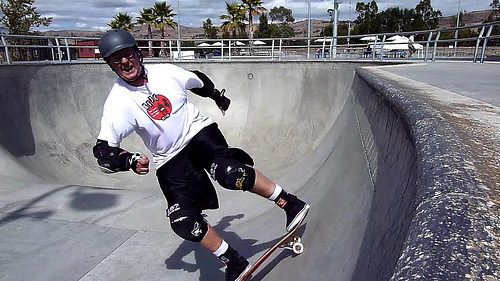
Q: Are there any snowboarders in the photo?
A: No, there are no snowboarders.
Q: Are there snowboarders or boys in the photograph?
A: No, there are no snowboarders or boys.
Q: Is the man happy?
A: Yes, the man is happy.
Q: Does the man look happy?
A: Yes, the man is happy.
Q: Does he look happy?
A: Yes, the man is happy.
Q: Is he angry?
A: No, the man is happy.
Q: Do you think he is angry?
A: No, the man is happy.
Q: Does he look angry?
A: No, the man is happy.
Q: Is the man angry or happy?
A: The man is happy.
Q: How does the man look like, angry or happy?
A: The man is happy.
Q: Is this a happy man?
A: Yes, this is a happy man.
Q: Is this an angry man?
A: No, this is a happy man.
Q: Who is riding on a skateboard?
A: The man is riding on a skateboard.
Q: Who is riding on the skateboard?
A: The man is riding on a skateboard.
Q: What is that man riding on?
A: The man is riding on a skateboard.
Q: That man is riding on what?
A: The man is riding on a skateboard.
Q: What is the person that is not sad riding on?
A: The man is riding on a skateboard.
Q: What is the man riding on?
A: The man is riding on a skateboard.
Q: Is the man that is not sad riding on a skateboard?
A: Yes, the man is riding on a skateboard.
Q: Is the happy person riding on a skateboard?
A: Yes, the man is riding on a skateboard.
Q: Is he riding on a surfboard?
A: No, the man is riding on a skateboard.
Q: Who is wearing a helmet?
A: The man is wearing a helmet.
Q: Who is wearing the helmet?
A: The man is wearing a helmet.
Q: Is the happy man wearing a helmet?
A: Yes, the man is wearing a helmet.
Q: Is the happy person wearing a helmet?
A: Yes, the man is wearing a helmet.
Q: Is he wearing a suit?
A: No, the man is wearing a helmet.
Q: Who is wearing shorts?
A: The man is wearing shorts.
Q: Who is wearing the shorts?
A: The man is wearing shorts.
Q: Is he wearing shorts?
A: Yes, the man is wearing shorts.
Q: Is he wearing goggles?
A: No, the man is wearing shorts.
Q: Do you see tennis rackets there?
A: No, there are no tennis rackets.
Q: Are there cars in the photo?
A: No, there are no cars.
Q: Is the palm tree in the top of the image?
A: Yes, the palm tree is in the top of the image.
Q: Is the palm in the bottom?
A: No, the palm is in the top of the image.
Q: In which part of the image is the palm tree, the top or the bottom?
A: The palm tree is in the top of the image.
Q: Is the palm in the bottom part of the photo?
A: No, the palm is in the top of the image.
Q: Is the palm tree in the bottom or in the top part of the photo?
A: The palm tree is in the top of the image.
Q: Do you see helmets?
A: Yes, there is a helmet.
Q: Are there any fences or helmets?
A: Yes, there is a helmet.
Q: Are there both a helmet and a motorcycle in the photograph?
A: No, there is a helmet but no motorcycles.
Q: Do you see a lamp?
A: No, there are no lamps.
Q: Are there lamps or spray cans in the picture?
A: No, there are no lamps or spray cans.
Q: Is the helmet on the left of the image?
A: Yes, the helmet is on the left of the image.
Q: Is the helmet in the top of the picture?
A: Yes, the helmet is in the top of the image.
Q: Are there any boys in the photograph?
A: No, there are no boys.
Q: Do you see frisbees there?
A: No, there are no frisbees.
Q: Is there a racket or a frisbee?
A: No, there are no frisbees or rackets.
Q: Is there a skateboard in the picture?
A: Yes, there is a skateboard.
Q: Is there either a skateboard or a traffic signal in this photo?
A: Yes, there is a skateboard.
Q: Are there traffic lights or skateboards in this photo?
A: Yes, there is a skateboard.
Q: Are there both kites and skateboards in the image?
A: No, there is a skateboard but no kites.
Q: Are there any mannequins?
A: No, there are no mannequins.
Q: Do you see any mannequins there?
A: No, there are no mannequins.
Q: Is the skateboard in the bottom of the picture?
A: Yes, the skateboard is in the bottom of the image.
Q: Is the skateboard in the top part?
A: No, the skateboard is in the bottom of the image.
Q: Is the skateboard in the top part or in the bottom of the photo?
A: The skateboard is in the bottom of the image.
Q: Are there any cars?
A: No, there are no cars.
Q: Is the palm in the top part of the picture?
A: Yes, the palm is in the top of the image.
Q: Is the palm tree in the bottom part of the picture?
A: No, the palm tree is in the top of the image.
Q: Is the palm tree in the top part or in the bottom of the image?
A: The palm tree is in the top of the image.